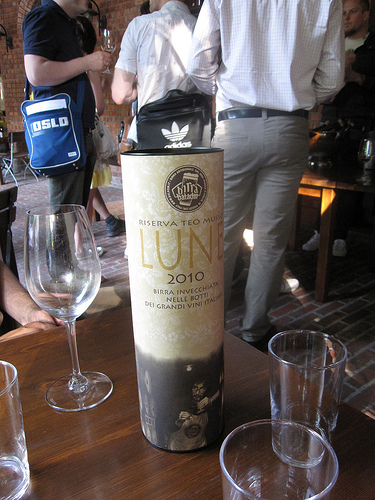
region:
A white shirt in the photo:
[124, 2, 196, 89]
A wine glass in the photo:
[25, 216, 87, 412]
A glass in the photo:
[269, 344, 337, 461]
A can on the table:
[123, 162, 237, 451]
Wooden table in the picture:
[93, 446, 170, 494]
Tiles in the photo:
[313, 307, 369, 340]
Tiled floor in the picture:
[305, 298, 370, 347]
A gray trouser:
[241, 138, 284, 207]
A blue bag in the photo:
[11, 90, 82, 172]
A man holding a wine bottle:
[14, 2, 123, 206]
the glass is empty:
[20, 204, 112, 411]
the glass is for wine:
[20, 202, 113, 411]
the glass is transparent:
[17, 203, 113, 412]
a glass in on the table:
[263, 328, 344, 467]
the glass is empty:
[264, 329, 345, 468]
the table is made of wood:
[0, 304, 370, 499]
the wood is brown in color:
[1, 295, 373, 496]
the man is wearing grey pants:
[202, 110, 310, 340]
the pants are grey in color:
[210, 105, 306, 347]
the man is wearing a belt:
[214, 103, 302, 121]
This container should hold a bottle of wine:
[110, 139, 247, 468]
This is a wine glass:
[15, 239, 129, 426]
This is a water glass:
[268, 323, 371, 475]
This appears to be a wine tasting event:
[7, 4, 357, 421]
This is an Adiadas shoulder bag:
[130, 86, 235, 161]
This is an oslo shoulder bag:
[17, 69, 105, 182]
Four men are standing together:
[12, 2, 374, 158]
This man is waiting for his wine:
[22, 0, 124, 99]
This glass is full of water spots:
[23, 205, 119, 344]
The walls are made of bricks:
[3, 4, 67, 97]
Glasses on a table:
[2, 201, 350, 497]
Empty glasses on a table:
[1, 198, 346, 498]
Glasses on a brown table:
[1, 201, 344, 497]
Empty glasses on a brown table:
[1, 201, 351, 497]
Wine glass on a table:
[24, 199, 121, 411]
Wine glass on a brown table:
[21, 199, 111, 409]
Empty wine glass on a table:
[23, 200, 113, 410]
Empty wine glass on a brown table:
[24, 200, 115, 412]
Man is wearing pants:
[209, 109, 311, 342]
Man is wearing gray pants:
[210, 109, 311, 343]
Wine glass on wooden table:
[23, 205, 115, 411]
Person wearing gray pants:
[185, 0, 348, 349]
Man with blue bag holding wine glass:
[23, 1, 112, 284]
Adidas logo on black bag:
[159, 117, 192, 150]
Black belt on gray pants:
[217, 109, 305, 120]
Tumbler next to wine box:
[267, 326, 350, 466]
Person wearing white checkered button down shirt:
[192, 0, 343, 345]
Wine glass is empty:
[24, 204, 117, 410]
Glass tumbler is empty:
[267, 326, 346, 469]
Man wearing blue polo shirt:
[21, 0, 112, 283]